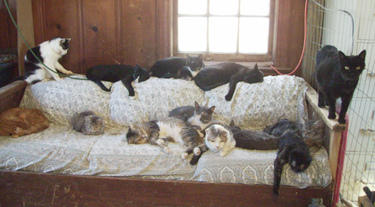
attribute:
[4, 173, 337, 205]
panel — wooden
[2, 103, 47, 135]
orange cat — balled-up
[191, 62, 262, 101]
cat — black 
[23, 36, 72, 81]
cat — black 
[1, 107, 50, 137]
brown cat — LAYING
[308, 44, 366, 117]
cat — black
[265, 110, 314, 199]
cat — black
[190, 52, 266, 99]
cat — black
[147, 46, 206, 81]
cat — black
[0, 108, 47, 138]
cat — orange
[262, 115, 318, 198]
cat — grey, brown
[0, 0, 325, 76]
wall — made of wood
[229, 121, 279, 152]
cat — grey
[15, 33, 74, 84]
cat — black, white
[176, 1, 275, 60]
window — open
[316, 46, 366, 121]
cat — black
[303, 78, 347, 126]
arm — futon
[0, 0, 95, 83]
cord — green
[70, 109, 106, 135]
cat — small, tabby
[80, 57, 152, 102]
cat — LAYING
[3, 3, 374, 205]
room — full of cats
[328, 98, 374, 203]
cage — tall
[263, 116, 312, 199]
cat — black 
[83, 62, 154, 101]
cat — black, white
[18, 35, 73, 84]
cat — grey , white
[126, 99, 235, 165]
cats — many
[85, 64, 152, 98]
cat — black 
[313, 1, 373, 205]
wall — metal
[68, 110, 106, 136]
grey cat — LAYING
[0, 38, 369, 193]
cats — laying 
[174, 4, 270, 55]
window — square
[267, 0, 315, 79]
cord — red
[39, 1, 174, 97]
paneled wall — wooden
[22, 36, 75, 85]
cat — white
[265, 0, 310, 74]
cord — orange, extension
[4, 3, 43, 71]
cord — green